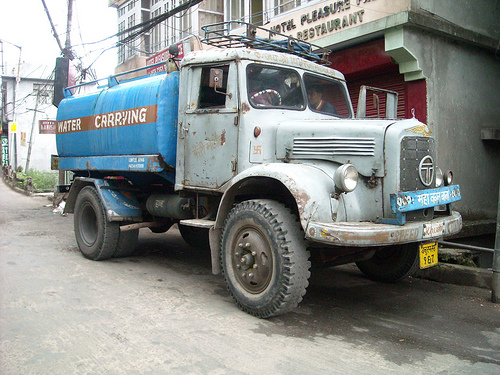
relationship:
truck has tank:
[45, 33, 466, 320] [48, 53, 179, 172]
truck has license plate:
[45, 33, 466, 320] [419, 243, 441, 270]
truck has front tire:
[45, 33, 466, 320] [217, 200, 313, 315]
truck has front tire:
[45, 33, 466, 320] [355, 245, 420, 282]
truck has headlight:
[45, 33, 466, 320] [331, 161, 358, 195]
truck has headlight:
[45, 33, 466, 320] [433, 167, 443, 185]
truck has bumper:
[45, 33, 466, 320] [309, 211, 468, 246]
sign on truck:
[54, 103, 163, 138] [45, 33, 466, 320]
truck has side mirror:
[45, 33, 466, 320] [206, 65, 224, 89]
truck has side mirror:
[45, 33, 466, 320] [371, 92, 382, 113]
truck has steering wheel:
[45, 33, 466, 320] [251, 88, 286, 108]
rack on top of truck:
[201, 21, 335, 67] [45, 33, 466, 320]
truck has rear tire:
[45, 33, 466, 320] [75, 187, 141, 263]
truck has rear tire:
[45, 33, 466, 320] [176, 221, 210, 248]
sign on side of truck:
[54, 103, 163, 138] [45, 33, 466, 320]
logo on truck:
[416, 155, 438, 188] [45, 33, 466, 320]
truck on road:
[45, 33, 466, 320] [1, 173, 499, 375]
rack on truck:
[201, 21, 335, 67] [45, 33, 466, 320]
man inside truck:
[303, 86, 334, 115] [45, 33, 466, 320]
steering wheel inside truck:
[251, 88, 286, 108] [45, 33, 466, 320]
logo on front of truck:
[416, 155, 438, 188] [45, 33, 466, 320]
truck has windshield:
[45, 33, 466, 320] [247, 60, 349, 121]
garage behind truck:
[323, 50, 423, 120] [45, 33, 466, 320]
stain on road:
[258, 278, 499, 369] [1, 173, 499, 375]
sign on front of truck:
[390, 187, 464, 206] [45, 33, 466, 320]